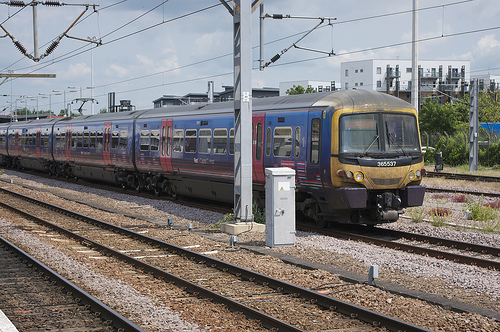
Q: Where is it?
A: This is at the pavement.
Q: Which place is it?
A: It is a pavement.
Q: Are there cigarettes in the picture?
A: No, there are no cigarettes.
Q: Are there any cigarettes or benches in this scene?
A: No, there are no cigarettes or benches.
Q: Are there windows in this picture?
A: Yes, there is a window.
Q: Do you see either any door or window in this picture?
A: Yes, there is a window.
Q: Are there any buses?
A: No, there are no buses.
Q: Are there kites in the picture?
A: No, there are no kites.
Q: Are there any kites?
A: No, there are no kites.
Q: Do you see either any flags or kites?
A: No, there are no kites or flags.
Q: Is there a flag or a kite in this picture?
A: No, there are no kites or flags.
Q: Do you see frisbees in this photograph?
A: No, there are no frisbees.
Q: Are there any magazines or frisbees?
A: No, there are no frisbees or magazines.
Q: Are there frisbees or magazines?
A: No, there are no frisbees or magazines.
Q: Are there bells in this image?
A: No, there are no bells.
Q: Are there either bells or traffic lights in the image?
A: No, there are no bells or traffic lights.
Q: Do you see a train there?
A: Yes, there is a train.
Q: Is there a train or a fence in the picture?
A: Yes, there is a train.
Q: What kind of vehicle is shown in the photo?
A: The vehicle is a train.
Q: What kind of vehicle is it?
A: The vehicle is a train.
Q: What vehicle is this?
A: This is a train.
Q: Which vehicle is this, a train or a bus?
A: This is a train.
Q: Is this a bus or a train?
A: This is a train.